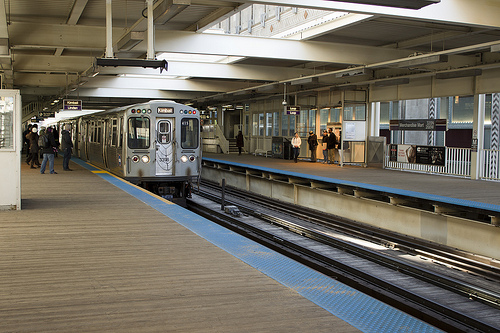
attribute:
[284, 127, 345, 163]
people — standing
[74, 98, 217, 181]
train — silver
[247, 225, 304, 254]
tracks — brown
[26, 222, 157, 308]
floor — brown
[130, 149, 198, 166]
headlights — on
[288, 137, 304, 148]
shirt — white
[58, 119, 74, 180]
person — standing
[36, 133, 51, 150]
backpack — gray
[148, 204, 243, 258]
floor — blue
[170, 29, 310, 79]
rafters — metal, white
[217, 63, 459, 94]
pipe — long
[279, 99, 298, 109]
light — off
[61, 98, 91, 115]
sign — hanging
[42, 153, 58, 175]
jeans — blue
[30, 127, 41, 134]
hat — white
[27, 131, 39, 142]
hair — long